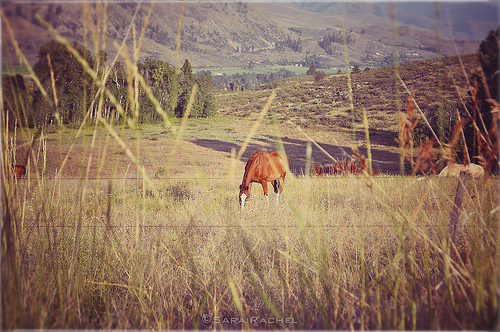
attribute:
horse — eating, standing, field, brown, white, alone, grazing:
[214, 146, 292, 211]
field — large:
[41, 115, 495, 301]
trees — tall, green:
[13, 37, 215, 124]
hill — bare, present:
[280, 45, 478, 130]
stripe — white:
[239, 191, 249, 209]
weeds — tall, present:
[24, 92, 151, 322]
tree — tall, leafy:
[394, 71, 419, 172]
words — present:
[193, 308, 310, 331]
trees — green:
[298, 56, 375, 78]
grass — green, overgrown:
[169, 194, 374, 240]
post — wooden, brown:
[452, 163, 472, 263]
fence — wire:
[37, 167, 457, 264]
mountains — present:
[73, 9, 468, 71]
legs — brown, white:
[257, 180, 294, 205]